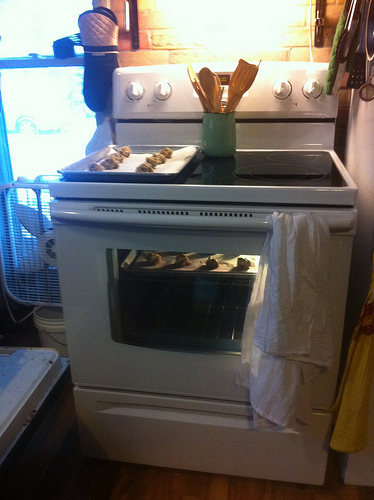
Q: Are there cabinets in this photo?
A: Yes, there is a cabinet.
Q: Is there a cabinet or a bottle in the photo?
A: Yes, there is a cabinet.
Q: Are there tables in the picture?
A: No, there are no tables.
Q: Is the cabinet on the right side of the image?
A: Yes, the cabinet is on the right of the image.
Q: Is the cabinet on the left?
A: No, the cabinet is on the right of the image.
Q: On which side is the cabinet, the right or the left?
A: The cabinet is on the right of the image.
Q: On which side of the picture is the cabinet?
A: The cabinet is on the right of the image.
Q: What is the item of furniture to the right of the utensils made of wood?
A: The piece of furniture is a cabinet.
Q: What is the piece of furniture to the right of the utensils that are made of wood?
A: The piece of furniture is a cabinet.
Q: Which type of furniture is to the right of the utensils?
A: The piece of furniture is a cabinet.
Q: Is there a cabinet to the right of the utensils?
A: Yes, there is a cabinet to the right of the utensils.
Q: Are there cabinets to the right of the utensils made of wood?
A: Yes, there is a cabinet to the right of the utensils.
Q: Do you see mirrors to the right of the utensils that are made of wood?
A: No, there is a cabinet to the right of the utensils.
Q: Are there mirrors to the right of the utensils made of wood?
A: No, there is a cabinet to the right of the utensils.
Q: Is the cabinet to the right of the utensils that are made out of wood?
A: Yes, the cabinet is to the right of the utensils.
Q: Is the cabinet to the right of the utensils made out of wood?
A: Yes, the cabinet is to the right of the utensils.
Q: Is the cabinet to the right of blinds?
A: No, the cabinet is to the right of the utensils.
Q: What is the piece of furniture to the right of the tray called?
A: The piece of furniture is a cabinet.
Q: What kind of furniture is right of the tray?
A: The piece of furniture is a cabinet.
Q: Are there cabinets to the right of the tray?
A: Yes, there is a cabinet to the right of the tray.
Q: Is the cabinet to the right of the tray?
A: Yes, the cabinet is to the right of the tray.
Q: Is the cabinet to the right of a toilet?
A: No, the cabinet is to the right of the tray.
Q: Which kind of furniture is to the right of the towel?
A: The piece of furniture is a cabinet.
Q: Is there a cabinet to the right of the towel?
A: Yes, there is a cabinet to the right of the towel.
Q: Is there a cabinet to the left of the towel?
A: No, the cabinet is to the right of the towel.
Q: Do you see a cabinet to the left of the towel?
A: No, the cabinet is to the right of the towel.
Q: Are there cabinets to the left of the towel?
A: No, the cabinet is to the right of the towel.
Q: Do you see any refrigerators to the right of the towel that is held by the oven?
A: No, there is a cabinet to the right of the towel.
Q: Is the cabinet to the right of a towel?
A: Yes, the cabinet is to the right of a towel.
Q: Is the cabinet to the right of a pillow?
A: No, the cabinet is to the right of a towel.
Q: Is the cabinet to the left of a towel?
A: No, the cabinet is to the right of a towel.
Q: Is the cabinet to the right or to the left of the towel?
A: The cabinet is to the right of the towel.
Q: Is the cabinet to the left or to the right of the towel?
A: The cabinet is to the right of the towel.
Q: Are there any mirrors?
A: No, there are no mirrors.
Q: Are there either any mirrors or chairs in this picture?
A: No, there are no mirrors or chairs.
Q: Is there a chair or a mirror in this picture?
A: No, there are no mirrors or chairs.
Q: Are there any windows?
A: Yes, there is a window.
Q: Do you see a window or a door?
A: Yes, there is a window.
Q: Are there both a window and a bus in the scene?
A: No, there is a window but no buses.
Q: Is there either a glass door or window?
A: Yes, there is a glass window.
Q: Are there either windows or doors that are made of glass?
A: Yes, the window is made of glass.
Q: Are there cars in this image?
A: No, there are no cars.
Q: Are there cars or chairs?
A: No, there are no cars or chairs.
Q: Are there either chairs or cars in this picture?
A: No, there are no cars or chairs.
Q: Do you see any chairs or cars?
A: No, there are no cars or chairs.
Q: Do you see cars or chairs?
A: No, there are no cars or chairs.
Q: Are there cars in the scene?
A: No, there are no cars.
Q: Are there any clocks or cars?
A: No, there are no cars or clocks.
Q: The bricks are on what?
A: The bricks are on the wall.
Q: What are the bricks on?
A: The bricks are on the wall.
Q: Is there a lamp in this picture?
A: No, there are no lamps.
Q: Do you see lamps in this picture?
A: No, there are no lamps.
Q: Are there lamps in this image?
A: No, there are no lamps.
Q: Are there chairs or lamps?
A: No, there are no lamps or chairs.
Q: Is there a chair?
A: No, there are no chairs.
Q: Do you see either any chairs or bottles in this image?
A: No, there are no chairs or bottles.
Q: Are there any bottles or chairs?
A: No, there are no chairs or bottles.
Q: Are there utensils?
A: Yes, there are utensils.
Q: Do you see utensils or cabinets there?
A: Yes, there are utensils.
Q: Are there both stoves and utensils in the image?
A: Yes, there are both utensils and a stove.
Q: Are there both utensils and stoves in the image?
A: Yes, there are both utensils and a stove.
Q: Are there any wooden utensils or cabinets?
A: Yes, there are wood utensils.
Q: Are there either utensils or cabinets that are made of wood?
A: Yes, the utensils are made of wood.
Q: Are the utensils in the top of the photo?
A: Yes, the utensils are in the top of the image.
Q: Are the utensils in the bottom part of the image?
A: No, the utensils are in the top of the image.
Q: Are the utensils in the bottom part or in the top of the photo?
A: The utensils are in the top of the image.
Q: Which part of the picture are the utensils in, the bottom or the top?
A: The utensils are in the top of the image.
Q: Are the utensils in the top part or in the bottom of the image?
A: The utensils are in the top of the image.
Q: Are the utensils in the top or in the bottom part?
A: The utensils are in the top of the image.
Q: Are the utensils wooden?
A: Yes, the utensils are wooden.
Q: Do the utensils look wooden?
A: Yes, the utensils are wooden.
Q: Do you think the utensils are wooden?
A: Yes, the utensils are wooden.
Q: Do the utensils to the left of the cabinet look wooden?
A: Yes, the utensils are wooden.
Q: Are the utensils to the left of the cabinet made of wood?
A: Yes, the utensils are made of wood.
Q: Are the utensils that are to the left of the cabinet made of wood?
A: Yes, the utensils are made of wood.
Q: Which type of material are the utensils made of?
A: The utensils are made of wood.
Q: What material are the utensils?
A: The utensils are made of wood.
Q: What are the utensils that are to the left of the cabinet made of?
A: The utensils are made of wood.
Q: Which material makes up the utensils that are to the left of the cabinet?
A: The utensils are made of wood.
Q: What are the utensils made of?
A: The utensils are made of wood.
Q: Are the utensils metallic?
A: No, the utensils are wooden.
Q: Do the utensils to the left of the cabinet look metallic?
A: No, the utensils are wooden.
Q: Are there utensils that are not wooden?
A: No, there are utensils but they are wooden.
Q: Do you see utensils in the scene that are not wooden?
A: No, there are utensils but they are wooden.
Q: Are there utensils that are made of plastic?
A: No, there are utensils but they are made of wood.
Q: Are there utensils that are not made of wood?
A: No, there are utensils but they are made of wood.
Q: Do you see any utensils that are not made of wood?
A: No, there are utensils but they are made of wood.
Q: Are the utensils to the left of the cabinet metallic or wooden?
A: The utensils are wooden.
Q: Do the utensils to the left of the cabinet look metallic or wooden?
A: The utensils are wooden.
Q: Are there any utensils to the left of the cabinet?
A: Yes, there are utensils to the left of the cabinet.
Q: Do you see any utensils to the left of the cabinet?
A: Yes, there are utensils to the left of the cabinet.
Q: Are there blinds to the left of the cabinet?
A: No, there are utensils to the left of the cabinet.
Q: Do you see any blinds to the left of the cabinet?
A: No, there are utensils to the left of the cabinet.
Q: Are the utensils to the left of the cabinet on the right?
A: Yes, the utensils are to the left of the cabinet.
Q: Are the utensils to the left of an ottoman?
A: No, the utensils are to the left of the cabinet.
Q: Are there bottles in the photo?
A: No, there are no bottles.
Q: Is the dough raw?
A: Yes, the dough is raw.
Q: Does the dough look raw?
A: Yes, the dough is raw.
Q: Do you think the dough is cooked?
A: No, the dough is raw.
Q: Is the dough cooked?
A: No, the dough is raw.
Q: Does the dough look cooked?
A: No, the dough is raw.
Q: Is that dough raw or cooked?
A: The dough is raw.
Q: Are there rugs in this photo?
A: No, there are no rugs.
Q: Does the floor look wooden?
A: Yes, the floor is wooden.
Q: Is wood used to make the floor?
A: Yes, the floor is made of wood.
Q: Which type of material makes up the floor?
A: The floor is made of wood.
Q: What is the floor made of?
A: The floor is made of wood.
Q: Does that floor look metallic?
A: No, the floor is wooden.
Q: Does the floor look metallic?
A: No, the floor is wooden.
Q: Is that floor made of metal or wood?
A: The floor is made of wood.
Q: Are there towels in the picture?
A: Yes, there is a towel.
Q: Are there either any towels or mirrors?
A: Yes, there is a towel.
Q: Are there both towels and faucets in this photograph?
A: No, there is a towel but no faucets.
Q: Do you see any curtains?
A: No, there are no curtains.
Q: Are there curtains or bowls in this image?
A: No, there are no curtains or bowls.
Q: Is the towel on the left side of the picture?
A: No, the towel is on the right of the image.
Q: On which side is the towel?
A: The towel is on the right of the image.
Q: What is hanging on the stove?
A: The towel is hanging on the stove.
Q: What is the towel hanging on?
A: The towel is hanging on the stove.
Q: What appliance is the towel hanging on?
A: The towel is hanging on the stove.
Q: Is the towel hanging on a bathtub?
A: No, the towel is hanging on a stove.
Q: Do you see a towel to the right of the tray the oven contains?
A: Yes, there is a towel to the right of the tray.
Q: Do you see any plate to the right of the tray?
A: No, there is a towel to the right of the tray.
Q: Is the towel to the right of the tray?
A: Yes, the towel is to the right of the tray.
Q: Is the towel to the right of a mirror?
A: No, the towel is to the right of the tray.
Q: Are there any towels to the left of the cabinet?
A: Yes, there is a towel to the left of the cabinet.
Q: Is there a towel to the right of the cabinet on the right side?
A: No, the towel is to the left of the cabinet.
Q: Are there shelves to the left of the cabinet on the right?
A: No, there is a towel to the left of the cabinet.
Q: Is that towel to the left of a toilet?
A: No, the towel is to the left of a cabinet.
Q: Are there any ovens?
A: Yes, there is an oven.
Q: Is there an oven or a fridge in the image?
A: Yes, there is an oven.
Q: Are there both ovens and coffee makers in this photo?
A: No, there is an oven but no coffee makers.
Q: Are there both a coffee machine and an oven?
A: No, there is an oven but no coffee makers.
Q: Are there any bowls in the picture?
A: No, there are no bowls.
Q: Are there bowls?
A: No, there are no bowls.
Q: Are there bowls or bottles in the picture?
A: No, there are no bowls or bottles.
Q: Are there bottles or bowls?
A: No, there are no bowls or bottles.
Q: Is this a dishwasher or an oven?
A: This is an oven.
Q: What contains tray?
A: The oven contains tray.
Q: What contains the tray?
A: The oven contains tray.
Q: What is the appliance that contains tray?
A: The appliance is an oven.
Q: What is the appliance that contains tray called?
A: The appliance is an oven.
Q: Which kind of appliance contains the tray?
A: The appliance is an oven.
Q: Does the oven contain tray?
A: Yes, the oven contains tray.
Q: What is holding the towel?
A: The oven is holding the towel.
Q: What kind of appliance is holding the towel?
A: The appliance is an oven.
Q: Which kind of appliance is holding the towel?
A: The appliance is an oven.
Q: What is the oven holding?
A: The oven is holding the towel.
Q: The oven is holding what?
A: The oven is holding the towel.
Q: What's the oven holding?
A: The oven is holding the towel.